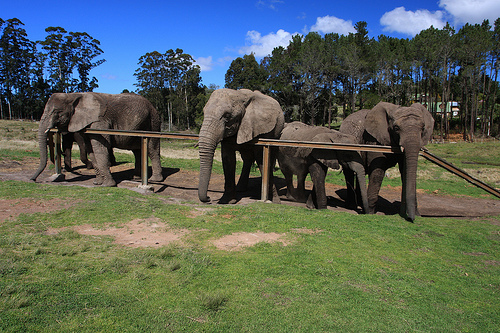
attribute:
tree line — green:
[225, 15, 491, 134]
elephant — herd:
[293, 125, 349, 184]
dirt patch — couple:
[211, 220, 322, 255]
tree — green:
[132, 45, 203, 136]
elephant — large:
[178, 85, 288, 214]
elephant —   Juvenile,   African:
[31, 85, 156, 170]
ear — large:
[244, 82, 289, 147]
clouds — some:
[249, 36, 290, 52]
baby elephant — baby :
[274, 117, 370, 209]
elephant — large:
[10, 84, 178, 199]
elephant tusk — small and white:
[394, 140, 408, 155]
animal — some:
[336, 100, 439, 224]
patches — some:
[41, 196, 351, 300]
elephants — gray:
[221, 66, 421, 238]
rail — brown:
[112, 120, 386, 187]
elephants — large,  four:
[20, 89, 435, 222]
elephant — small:
[277, 116, 378, 229]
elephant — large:
[171, 79, 294, 226]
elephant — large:
[330, 100, 439, 214]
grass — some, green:
[0, 134, 483, 330]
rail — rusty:
[240, 141, 376, 184]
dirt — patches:
[141, 210, 264, 274]